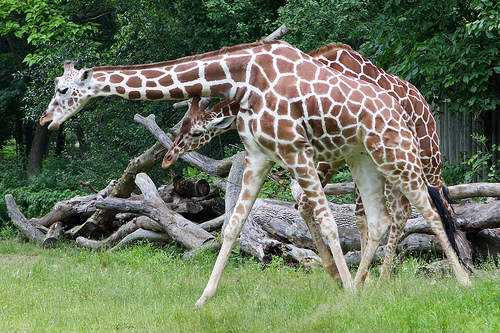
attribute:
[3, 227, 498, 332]
grass — green, here, tall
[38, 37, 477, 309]
giraffe — brown, white, here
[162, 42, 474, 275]
giraffe — brown, white, here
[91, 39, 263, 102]
neck — long, spotted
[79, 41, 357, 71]
fur — brown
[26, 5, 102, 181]
tree — here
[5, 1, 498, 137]
leaves — dense, large, green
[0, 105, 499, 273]
logs — here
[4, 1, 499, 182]
trees — tall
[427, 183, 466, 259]
hair — black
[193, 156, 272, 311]
leg — long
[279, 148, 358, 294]
leg — long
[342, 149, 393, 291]
leg — long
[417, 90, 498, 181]
fence — tall, wooden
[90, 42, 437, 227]
spots — brown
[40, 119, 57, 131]
mouth — open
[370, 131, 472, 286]
leg — long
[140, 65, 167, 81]
spot — brown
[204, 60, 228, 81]
spot — brown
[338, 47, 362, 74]
spot — brown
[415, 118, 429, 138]
spot — brown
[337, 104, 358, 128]
spot — brown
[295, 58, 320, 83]
spot — brown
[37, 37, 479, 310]
animals — wild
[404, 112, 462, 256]
tail — long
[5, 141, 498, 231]
bushes — thick